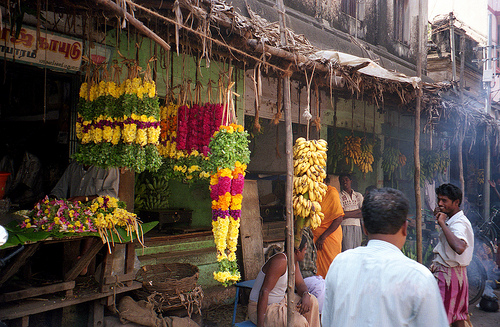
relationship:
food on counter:
[29, 197, 128, 236] [83, 276, 119, 301]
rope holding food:
[213, 70, 253, 137] [195, 121, 256, 265]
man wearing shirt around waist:
[420, 180, 472, 325] [428, 255, 475, 284]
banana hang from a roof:
[283, 128, 329, 231] [230, 46, 342, 82]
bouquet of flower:
[24, 207, 133, 237] [145, 84, 168, 167]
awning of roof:
[283, 47, 403, 83] [144, 2, 466, 123]